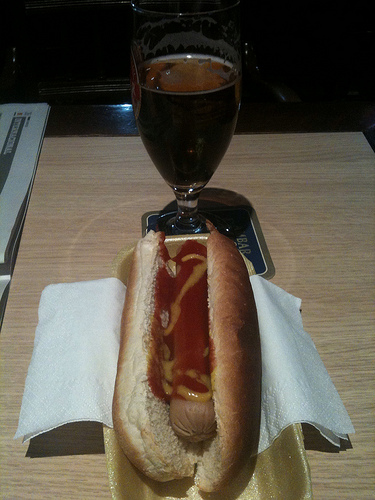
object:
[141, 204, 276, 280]
coaster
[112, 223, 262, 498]
bun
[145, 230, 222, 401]
condiment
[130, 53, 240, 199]
beer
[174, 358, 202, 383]
mustard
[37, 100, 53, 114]
corner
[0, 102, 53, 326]
newspaper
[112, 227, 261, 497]
hot dog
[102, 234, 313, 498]
tray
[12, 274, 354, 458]
napkin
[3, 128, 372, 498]
table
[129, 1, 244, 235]
glass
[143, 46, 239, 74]
foam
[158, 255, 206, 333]
cheese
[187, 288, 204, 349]
ketchup